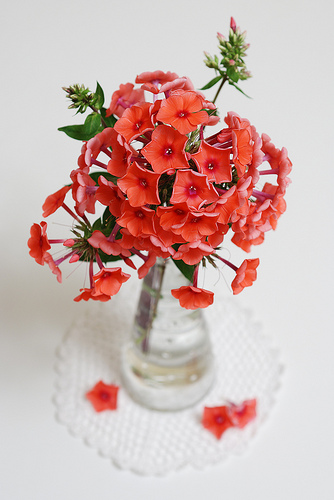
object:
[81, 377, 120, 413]
flower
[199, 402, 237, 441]
flower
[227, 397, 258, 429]
flower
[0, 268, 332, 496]
ground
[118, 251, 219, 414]
flower vase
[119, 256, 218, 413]
water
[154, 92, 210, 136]
flower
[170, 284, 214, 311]
flower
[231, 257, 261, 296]
flower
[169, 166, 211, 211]
flower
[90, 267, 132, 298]
flower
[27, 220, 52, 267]
flower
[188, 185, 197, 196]
purple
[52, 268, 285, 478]
doylie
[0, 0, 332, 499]
table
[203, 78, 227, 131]
stem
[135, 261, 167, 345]
stem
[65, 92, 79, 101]
flower bud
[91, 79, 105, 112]
leaf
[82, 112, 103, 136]
leaf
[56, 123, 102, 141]
leaf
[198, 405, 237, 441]
fallen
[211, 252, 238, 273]
strand